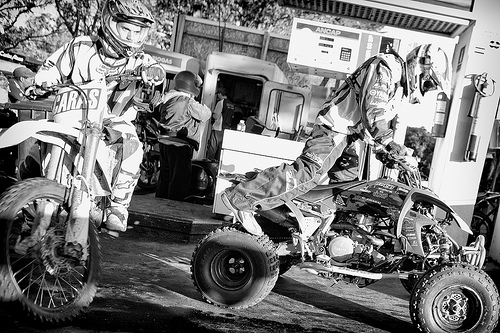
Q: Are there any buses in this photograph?
A: No, there are no buses.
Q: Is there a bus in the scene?
A: No, there are no buses.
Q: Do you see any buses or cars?
A: No, there are no buses or cars.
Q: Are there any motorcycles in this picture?
A: Yes, there is a motorcycle.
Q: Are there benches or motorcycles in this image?
A: Yes, there is a motorcycle.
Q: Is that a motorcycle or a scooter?
A: That is a motorcycle.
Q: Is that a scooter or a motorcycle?
A: That is a motorcycle.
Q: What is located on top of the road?
A: The motorbike is on top of the road.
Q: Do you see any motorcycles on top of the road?
A: Yes, there is a motorcycle on top of the road.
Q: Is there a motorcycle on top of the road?
A: Yes, there is a motorcycle on top of the road.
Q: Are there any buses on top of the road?
A: No, there is a motorcycle on top of the road.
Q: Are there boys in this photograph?
A: No, there are no boys.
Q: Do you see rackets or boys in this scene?
A: No, there are no boys or rackets.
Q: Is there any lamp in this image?
A: No, there are no lamps.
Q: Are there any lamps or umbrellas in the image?
A: No, there are no lamps or umbrellas.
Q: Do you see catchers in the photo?
A: No, there are no catchers.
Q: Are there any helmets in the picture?
A: Yes, there is a helmet.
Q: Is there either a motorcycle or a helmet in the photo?
A: Yes, there is a helmet.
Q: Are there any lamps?
A: No, there are no lamps.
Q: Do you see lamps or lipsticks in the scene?
A: No, there are no lamps or lipsticks.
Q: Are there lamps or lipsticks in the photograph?
A: No, there are no lamps or lipsticks.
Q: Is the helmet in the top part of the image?
A: Yes, the helmet is in the top of the image.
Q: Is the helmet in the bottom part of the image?
A: No, the helmet is in the top of the image.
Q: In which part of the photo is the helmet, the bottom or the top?
A: The helmet is in the top of the image.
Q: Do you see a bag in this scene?
A: No, there are no bags.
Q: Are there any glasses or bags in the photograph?
A: No, there are no bags or glasses.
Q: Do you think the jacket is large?
A: Yes, the jacket is large.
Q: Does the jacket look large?
A: Yes, the jacket is large.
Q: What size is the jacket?
A: The jacket is large.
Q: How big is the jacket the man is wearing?
A: The jacket is large.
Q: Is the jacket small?
A: No, the jacket is large.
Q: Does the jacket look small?
A: No, the jacket is large.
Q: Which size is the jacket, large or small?
A: The jacket is large.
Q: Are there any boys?
A: No, there are no boys.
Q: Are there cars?
A: No, there are no cars.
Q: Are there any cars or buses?
A: No, there are no cars or buses.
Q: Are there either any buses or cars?
A: No, there are no cars or buses.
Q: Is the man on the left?
A: Yes, the man is on the left of the image.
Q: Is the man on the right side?
A: No, the man is on the left of the image.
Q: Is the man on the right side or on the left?
A: The man is on the left of the image.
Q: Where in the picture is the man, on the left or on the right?
A: The man is on the left of the image.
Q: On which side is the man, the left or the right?
A: The man is on the left of the image.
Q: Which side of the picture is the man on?
A: The man is on the left of the image.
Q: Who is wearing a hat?
A: The man is wearing a hat.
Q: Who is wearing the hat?
A: The man is wearing a hat.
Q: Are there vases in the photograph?
A: No, there are no vases.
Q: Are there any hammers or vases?
A: No, there are no vases or hammers.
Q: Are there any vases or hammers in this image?
A: No, there are no vases or hammers.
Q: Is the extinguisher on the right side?
A: Yes, the extinguisher is on the right of the image.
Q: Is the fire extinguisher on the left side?
A: No, the fire extinguisher is on the right of the image.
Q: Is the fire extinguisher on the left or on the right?
A: The fire extinguisher is on the right of the image.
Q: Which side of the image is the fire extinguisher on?
A: The fire extinguisher is on the right of the image.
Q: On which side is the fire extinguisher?
A: The fire extinguisher is on the right of the image.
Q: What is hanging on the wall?
A: The fire extinguisher is hanging on the wall.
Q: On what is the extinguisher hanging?
A: The extinguisher is hanging on the wall.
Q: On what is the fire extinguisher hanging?
A: The extinguisher is hanging on the wall.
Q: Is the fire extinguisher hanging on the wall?
A: Yes, the fire extinguisher is hanging on the wall.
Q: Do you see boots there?
A: Yes, there are boots.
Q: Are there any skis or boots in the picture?
A: Yes, there are boots.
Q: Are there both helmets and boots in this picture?
A: Yes, there are both boots and a helmet.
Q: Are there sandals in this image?
A: No, there are no sandals.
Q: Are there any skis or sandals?
A: No, there are no sandals or skis.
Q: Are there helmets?
A: Yes, there is a helmet.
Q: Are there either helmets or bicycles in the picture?
A: Yes, there is a helmet.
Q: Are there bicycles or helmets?
A: Yes, there is a helmet.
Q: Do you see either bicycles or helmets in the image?
A: Yes, there is a helmet.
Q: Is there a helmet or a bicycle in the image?
A: Yes, there is a helmet.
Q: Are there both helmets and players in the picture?
A: No, there is a helmet but no players.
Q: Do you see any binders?
A: No, there are no binders.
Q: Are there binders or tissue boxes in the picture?
A: No, there are no binders or tissue boxes.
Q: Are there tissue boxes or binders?
A: No, there are no binders or tissue boxes.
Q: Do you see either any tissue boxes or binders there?
A: No, there are no binders or tissue boxes.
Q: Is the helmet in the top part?
A: Yes, the helmet is in the top of the image.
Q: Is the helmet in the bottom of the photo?
A: No, the helmet is in the top of the image.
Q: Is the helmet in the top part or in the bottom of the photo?
A: The helmet is in the top of the image.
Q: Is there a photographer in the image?
A: No, there are no photographers.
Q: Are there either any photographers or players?
A: No, there are no photographers or players.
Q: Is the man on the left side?
A: Yes, the man is on the left of the image.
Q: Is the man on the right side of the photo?
A: No, the man is on the left of the image.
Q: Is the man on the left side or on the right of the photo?
A: The man is on the left of the image.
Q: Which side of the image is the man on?
A: The man is on the left of the image.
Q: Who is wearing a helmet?
A: The man is wearing a helmet.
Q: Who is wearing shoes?
A: The man is wearing shoes.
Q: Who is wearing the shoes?
A: The man is wearing shoes.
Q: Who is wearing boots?
A: The man is wearing boots.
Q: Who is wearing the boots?
A: The man is wearing boots.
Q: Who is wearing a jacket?
A: The man is wearing a jacket.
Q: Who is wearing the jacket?
A: The man is wearing a jacket.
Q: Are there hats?
A: Yes, there is a hat.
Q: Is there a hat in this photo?
A: Yes, there is a hat.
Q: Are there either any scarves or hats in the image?
A: Yes, there is a hat.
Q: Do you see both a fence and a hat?
A: Yes, there are both a hat and a fence.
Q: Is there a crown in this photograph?
A: No, there are no crowns.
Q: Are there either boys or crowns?
A: No, there are no crowns or boys.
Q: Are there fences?
A: Yes, there is a fence.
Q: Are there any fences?
A: Yes, there is a fence.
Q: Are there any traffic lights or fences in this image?
A: Yes, there is a fence.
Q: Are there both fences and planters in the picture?
A: No, there is a fence but no planters.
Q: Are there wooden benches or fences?
A: Yes, there is a wood fence.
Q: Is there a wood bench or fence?
A: Yes, there is a wood fence.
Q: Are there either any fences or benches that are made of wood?
A: Yes, the fence is made of wood.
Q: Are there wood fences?
A: Yes, there is a fence that is made of wood.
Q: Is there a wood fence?
A: Yes, there is a fence that is made of wood.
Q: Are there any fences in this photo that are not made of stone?
A: Yes, there is a fence that is made of wood.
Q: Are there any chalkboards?
A: No, there are no chalkboards.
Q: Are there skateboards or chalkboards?
A: No, there are no chalkboards or skateboards.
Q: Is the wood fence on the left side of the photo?
A: Yes, the fence is on the left of the image.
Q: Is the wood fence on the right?
A: No, the fence is on the left of the image.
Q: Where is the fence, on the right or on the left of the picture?
A: The fence is on the left of the image.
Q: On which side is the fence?
A: The fence is on the left of the image.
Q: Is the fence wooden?
A: Yes, the fence is wooden.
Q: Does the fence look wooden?
A: Yes, the fence is wooden.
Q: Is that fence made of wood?
A: Yes, the fence is made of wood.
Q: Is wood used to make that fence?
A: Yes, the fence is made of wood.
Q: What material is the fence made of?
A: The fence is made of wood.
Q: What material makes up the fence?
A: The fence is made of wood.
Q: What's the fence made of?
A: The fence is made of wood.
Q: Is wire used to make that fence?
A: No, the fence is made of wood.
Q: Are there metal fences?
A: No, there is a fence but it is made of wood.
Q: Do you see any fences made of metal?
A: No, there is a fence but it is made of wood.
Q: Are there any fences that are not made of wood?
A: No, there is a fence but it is made of wood.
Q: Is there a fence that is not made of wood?
A: No, there is a fence but it is made of wood.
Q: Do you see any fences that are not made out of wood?
A: No, there is a fence but it is made of wood.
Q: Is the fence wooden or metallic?
A: The fence is wooden.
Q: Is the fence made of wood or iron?
A: The fence is made of wood.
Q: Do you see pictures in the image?
A: No, there are no pictures.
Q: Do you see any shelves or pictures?
A: No, there are no pictures or shelves.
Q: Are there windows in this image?
A: Yes, there is a window.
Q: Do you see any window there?
A: Yes, there is a window.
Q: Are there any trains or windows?
A: Yes, there is a window.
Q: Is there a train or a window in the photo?
A: Yes, there is a window.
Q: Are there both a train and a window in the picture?
A: No, there is a window but no trains.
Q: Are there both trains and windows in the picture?
A: No, there is a window but no trains.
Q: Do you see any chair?
A: No, there are no chairs.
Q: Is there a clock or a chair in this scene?
A: No, there are no chairs or clocks.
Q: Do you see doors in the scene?
A: Yes, there is a door.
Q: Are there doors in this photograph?
A: Yes, there is a door.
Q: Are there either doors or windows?
A: Yes, there is a door.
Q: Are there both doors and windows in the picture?
A: Yes, there are both a door and a window.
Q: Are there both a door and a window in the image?
A: Yes, there are both a door and a window.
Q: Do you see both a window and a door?
A: Yes, there are both a door and a window.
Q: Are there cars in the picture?
A: No, there are no cars.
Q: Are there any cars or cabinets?
A: No, there are no cars or cabinets.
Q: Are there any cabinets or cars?
A: No, there are no cars or cabinets.